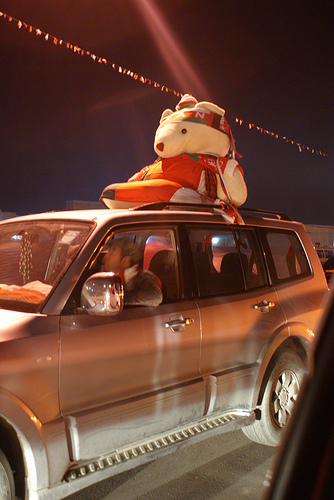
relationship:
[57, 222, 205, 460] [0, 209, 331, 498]
side door on suv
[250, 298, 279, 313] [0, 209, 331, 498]
handle on suv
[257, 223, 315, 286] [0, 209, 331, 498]
window on suv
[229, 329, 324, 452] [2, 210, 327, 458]
tire on car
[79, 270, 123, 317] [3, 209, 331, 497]
mirror on car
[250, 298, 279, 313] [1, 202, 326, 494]
handle on vehicle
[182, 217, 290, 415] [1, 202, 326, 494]
side door on vehicle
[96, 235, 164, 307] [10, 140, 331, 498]
person driving car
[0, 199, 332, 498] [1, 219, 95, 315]
windshield on vehicle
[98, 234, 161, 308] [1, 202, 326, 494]
man driving vehicle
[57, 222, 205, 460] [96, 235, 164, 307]
side door for person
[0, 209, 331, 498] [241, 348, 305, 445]
suv with tire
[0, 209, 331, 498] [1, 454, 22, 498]
suv with tire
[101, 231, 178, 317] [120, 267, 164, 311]
man in coat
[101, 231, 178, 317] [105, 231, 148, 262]
man in hat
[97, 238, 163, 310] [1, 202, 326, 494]
man driving vehicle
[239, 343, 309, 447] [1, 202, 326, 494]
tire on vehicle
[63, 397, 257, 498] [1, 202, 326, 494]
running board on vehicle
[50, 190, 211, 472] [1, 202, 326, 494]
driver door on vehicle